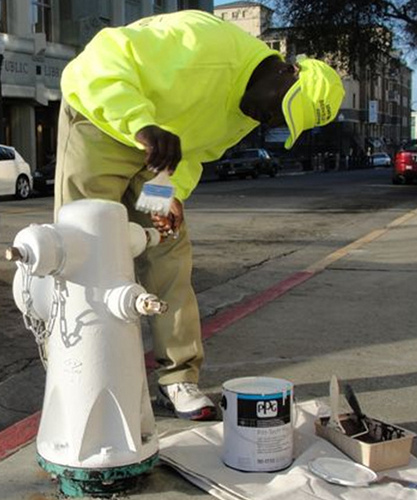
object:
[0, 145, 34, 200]
car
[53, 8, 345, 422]
man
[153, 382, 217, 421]
shoe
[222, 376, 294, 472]
can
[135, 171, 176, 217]
paint brush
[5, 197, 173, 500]
fire hydrand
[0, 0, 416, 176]
building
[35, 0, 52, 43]
window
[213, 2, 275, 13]
roof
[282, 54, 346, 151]
hat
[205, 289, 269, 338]
curb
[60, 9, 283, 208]
jacket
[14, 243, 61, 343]
chain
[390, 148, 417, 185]
car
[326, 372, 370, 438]
untensils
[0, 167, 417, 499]
street